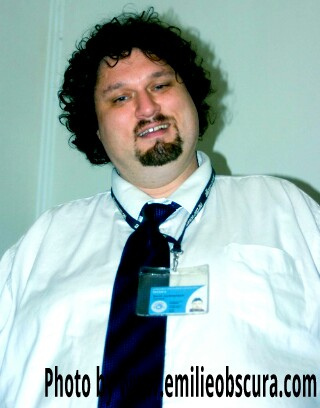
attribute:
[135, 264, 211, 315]
badge holder — plastic